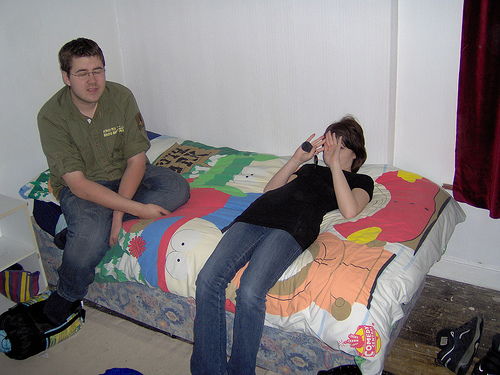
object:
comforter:
[19, 129, 467, 360]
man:
[38, 36, 191, 325]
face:
[69, 58, 104, 100]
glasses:
[67, 66, 106, 81]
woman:
[188, 112, 379, 375]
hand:
[293, 130, 327, 160]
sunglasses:
[301, 140, 321, 171]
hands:
[320, 129, 344, 165]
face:
[325, 133, 348, 169]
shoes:
[433, 312, 485, 372]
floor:
[1, 272, 500, 374]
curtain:
[447, 0, 500, 219]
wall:
[114, 0, 499, 287]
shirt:
[98, 366, 148, 374]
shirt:
[218, 162, 374, 242]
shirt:
[37, 80, 151, 201]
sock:
[53, 224, 76, 251]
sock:
[42, 291, 75, 326]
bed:
[17, 130, 467, 374]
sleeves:
[39, 108, 86, 186]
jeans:
[189, 217, 303, 373]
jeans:
[56, 163, 192, 305]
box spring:
[31, 215, 431, 374]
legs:
[231, 221, 308, 374]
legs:
[56, 180, 123, 301]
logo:
[339, 321, 385, 358]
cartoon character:
[126, 215, 224, 303]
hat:
[127, 217, 195, 289]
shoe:
[472, 333, 500, 374]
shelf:
[0, 193, 37, 224]